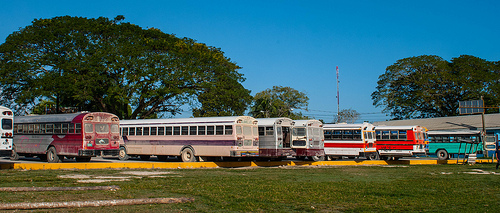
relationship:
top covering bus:
[424, 128, 484, 134] [426, 129, 484, 160]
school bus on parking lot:
[8, 103, 129, 163] [2, 148, 496, 173]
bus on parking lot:
[121, 115, 264, 164] [1, 152, 493, 170]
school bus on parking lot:
[259, 114, 300, 166] [4, 148, 498, 164]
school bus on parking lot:
[288, 112, 328, 164] [8, 155, 498, 173]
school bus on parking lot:
[373, 121, 429, 159] [255, 152, 493, 173]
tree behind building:
[364, 52, 498, 112] [397, 115, 493, 135]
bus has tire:
[430, 124, 490, 165] [433, 144, 451, 165]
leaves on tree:
[452, 61, 476, 89] [365, 43, 498, 122]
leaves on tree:
[452, 61, 476, 89] [371, 51, 499, 130]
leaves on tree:
[213, 67, 241, 104] [6, 11, 252, 124]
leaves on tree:
[94, 81, 128, 101] [6, 14, 256, 117]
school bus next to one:
[373, 125, 430, 160] [427, 127, 484, 157]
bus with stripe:
[324, 122, 377, 162] [316, 141, 381, 150]